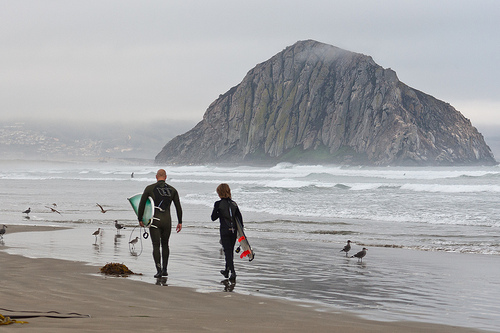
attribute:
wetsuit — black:
[141, 177, 171, 280]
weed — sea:
[81, 250, 146, 280]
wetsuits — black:
[212, 196, 245, 286]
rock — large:
[153, 38, 498, 168]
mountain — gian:
[201, 39, 443, 176]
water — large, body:
[3, 119, 497, 319]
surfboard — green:
[124, 190, 159, 230]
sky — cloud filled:
[18, 10, 148, 80]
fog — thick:
[9, 11, 241, 100]